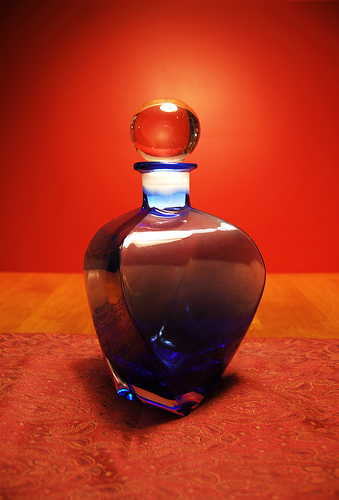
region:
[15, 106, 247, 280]
the wall is red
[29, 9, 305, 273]
the wall is red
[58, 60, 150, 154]
the wall is red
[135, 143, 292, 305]
the wall is red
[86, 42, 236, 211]
the wall is red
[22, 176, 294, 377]
the wall is red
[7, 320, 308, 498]
a dark red cloth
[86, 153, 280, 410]
a blue glass vase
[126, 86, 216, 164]
a clear glass top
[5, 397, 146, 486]
a red and gold paisley print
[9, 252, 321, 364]
a light wood table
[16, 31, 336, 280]
a red contrast wall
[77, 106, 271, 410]
a glass carafe with topper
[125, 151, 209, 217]
a dark blue bottle neck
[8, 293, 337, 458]
red tablecloth on wood table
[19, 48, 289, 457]
vase on a red cloth